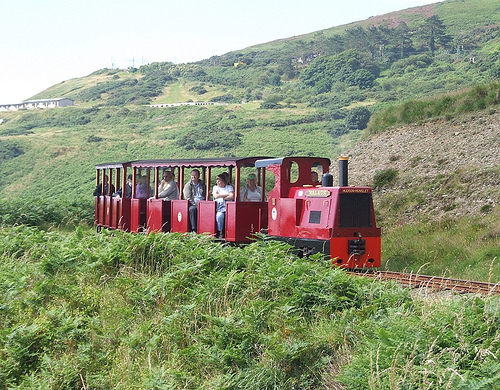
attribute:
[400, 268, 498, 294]
tracks — red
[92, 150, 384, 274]
train — red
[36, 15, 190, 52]
sky — gray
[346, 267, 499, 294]
tracks — steel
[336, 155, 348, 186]
black funnel — small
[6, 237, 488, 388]
grass — lush, green, lots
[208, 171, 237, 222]
woman — looking back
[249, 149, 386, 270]
engine — in front